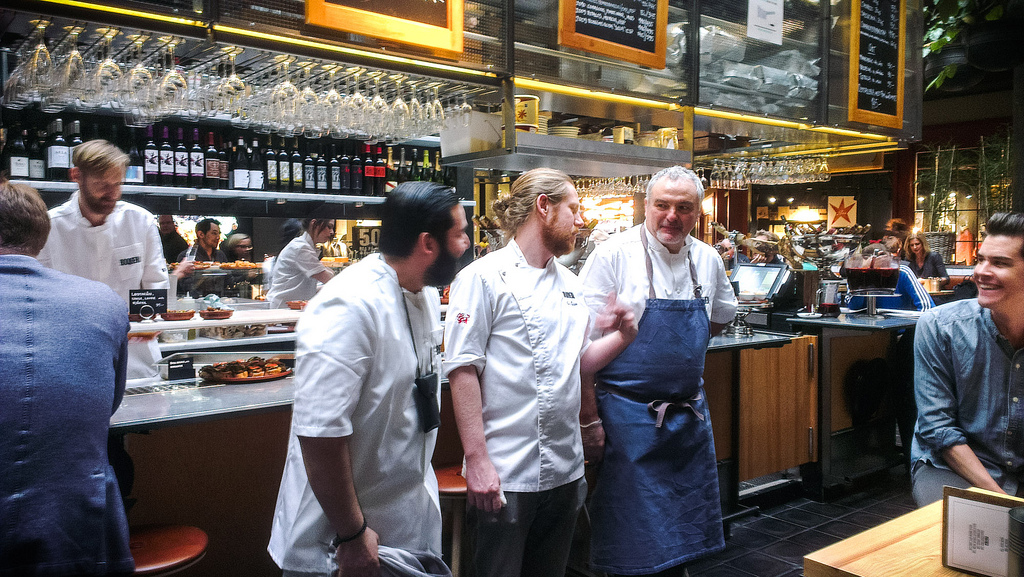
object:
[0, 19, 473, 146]
glasses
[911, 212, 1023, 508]
man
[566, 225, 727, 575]
apron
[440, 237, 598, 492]
coat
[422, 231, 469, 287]
beard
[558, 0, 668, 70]
frame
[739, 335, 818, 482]
door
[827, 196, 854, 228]
star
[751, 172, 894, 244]
wall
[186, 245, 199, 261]
vessel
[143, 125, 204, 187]
drinking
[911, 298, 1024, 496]
shirt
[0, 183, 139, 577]
man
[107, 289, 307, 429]
bar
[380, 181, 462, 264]
hair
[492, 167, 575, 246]
hair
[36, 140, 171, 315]
chef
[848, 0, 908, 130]
chalkboards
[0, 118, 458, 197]
bottles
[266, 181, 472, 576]
man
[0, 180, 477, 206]
shelf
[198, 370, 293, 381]
tray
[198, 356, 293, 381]
food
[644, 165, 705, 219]
hair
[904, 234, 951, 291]
woman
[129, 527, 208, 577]
stools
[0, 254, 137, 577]
coat